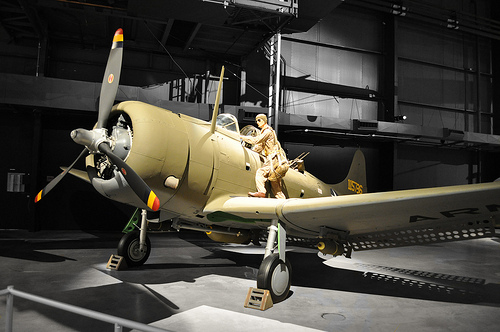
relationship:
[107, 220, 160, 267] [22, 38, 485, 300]
wheel attached to plane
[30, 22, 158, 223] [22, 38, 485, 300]
prop attached to plane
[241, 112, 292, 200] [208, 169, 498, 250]
man on top of wing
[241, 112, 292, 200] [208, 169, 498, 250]
man standing on wing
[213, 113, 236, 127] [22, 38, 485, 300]
windshield attached to plane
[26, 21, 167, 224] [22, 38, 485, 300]
propeller attached to plane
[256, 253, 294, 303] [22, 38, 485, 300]
wheel are attached to plane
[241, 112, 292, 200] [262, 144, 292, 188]
man wearing bag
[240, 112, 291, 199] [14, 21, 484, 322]
mannequin on airplane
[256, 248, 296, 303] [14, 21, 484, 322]
wheel on airplane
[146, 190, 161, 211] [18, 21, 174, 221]
stripe on propellers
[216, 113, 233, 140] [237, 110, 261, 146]
windshield for cockpit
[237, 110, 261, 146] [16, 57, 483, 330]
cockpit on plane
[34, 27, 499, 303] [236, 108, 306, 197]
airplane with mannequin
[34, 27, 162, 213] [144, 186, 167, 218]
propeller with stripes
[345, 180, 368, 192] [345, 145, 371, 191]
numbers on fin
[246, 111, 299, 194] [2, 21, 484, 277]
man climbing plane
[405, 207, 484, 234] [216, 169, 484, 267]
lettering on wing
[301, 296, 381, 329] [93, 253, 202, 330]
floor with shadows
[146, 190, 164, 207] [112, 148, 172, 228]
stripe on propeller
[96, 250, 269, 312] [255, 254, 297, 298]
blocks keeping wheels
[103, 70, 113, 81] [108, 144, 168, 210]
writing on fin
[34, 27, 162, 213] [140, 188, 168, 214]
propeller with stripes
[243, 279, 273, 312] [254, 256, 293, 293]
wedge on wheel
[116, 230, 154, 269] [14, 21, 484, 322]
wheel on airplane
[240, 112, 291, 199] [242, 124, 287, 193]
mannequin in uniform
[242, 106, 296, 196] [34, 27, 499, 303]
mannequin on airplane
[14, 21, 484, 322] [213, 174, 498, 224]
airplane has wing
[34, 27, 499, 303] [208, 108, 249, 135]
airplane has cockpit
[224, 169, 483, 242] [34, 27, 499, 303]
wing of airplane